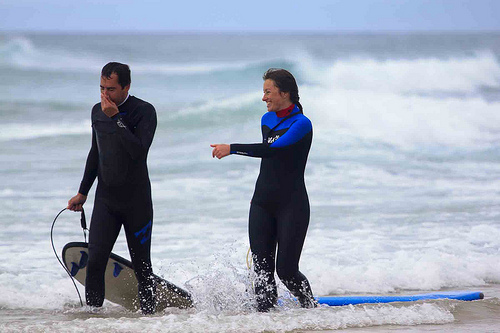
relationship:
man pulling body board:
[65, 60, 158, 316] [61, 240, 195, 312]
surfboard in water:
[271, 288, 487, 307] [1, 28, 498, 330]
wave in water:
[0, 83, 499, 165] [124, 39, 219, 117]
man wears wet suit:
[68, 60, 156, 315] [78, 95, 158, 307]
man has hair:
[65, 60, 158, 316] [101, 55, 131, 83]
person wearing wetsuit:
[207, 69, 322, 311] [232, 104, 312, 316]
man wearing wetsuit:
[65, 60, 158, 316] [76, 90, 160, 319]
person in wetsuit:
[207, 65, 319, 313] [232, 104, 312, 316]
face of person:
[261, 78, 280, 113] [207, 65, 319, 313]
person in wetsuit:
[207, 69, 322, 311] [229, 109, 311, 309]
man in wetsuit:
[65, 60, 158, 316] [74, 99, 158, 306]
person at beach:
[207, 69, 322, 311] [30, 284, 492, 331]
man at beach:
[65, 60, 158, 316] [30, 284, 492, 331]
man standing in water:
[68, 60, 156, 315] [1, 28, 498, 330]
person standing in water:
[207, 65, 319, 313] [1, 28, 498, 330]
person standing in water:
[207, 65, 319, 313] [33, 29, 497, 276]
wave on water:
[304, 57, 499, 163] [1, 28, 498, 330]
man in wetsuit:
[65, 60, 158, 316] [87, 101, 148, 310]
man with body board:
[65, 60, 158, 316] [68, 240, 190, 308]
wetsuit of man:
[76, 90, 160, 319] [74, 21, 175, 303]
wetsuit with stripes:
[76, 90, 160, 319] [131, 219, 153, 249]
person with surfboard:
[207, 65, 319, 313] [279, 292, 487, 307]